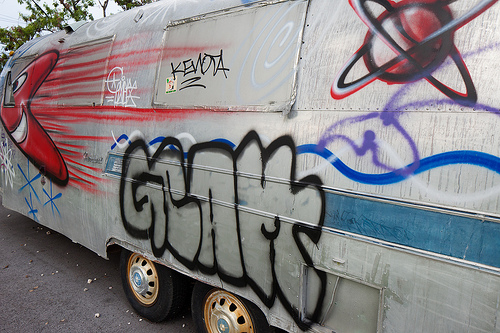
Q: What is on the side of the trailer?
A: Graffiti.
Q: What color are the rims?
A: Gold and silver.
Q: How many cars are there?
A: None.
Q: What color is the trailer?
A: Silver.